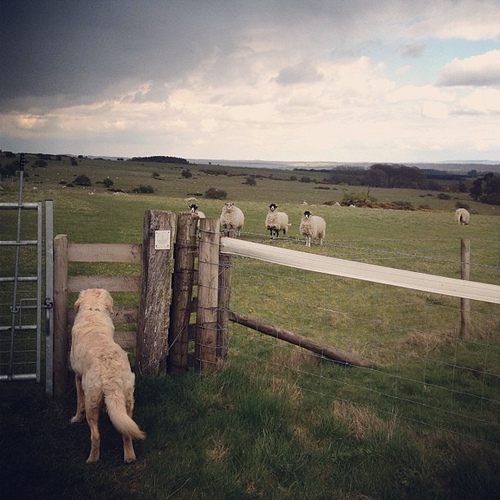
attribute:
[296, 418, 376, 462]
grass — part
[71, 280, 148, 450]
dog — big white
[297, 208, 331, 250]
sheep — four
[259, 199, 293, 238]
sheep — four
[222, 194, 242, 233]
sheep — four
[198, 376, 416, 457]
ground — part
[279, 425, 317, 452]
grass — part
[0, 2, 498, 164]
clouds — full 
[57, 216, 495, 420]
fence — wood, wire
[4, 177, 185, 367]
gate — Iron 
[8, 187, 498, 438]
fence — part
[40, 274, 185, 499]
dog — furry, white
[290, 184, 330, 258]
sheep — white ,  black face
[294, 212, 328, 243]
sheep — white 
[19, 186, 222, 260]
grass — large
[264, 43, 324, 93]
cloud — part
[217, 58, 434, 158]
clouds — white 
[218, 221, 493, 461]
gate — wire 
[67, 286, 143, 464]
dog — white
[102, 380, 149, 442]
tail — part,  long 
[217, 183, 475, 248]
sheep — four 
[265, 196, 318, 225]
faces — black 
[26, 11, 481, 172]
sky —  blue